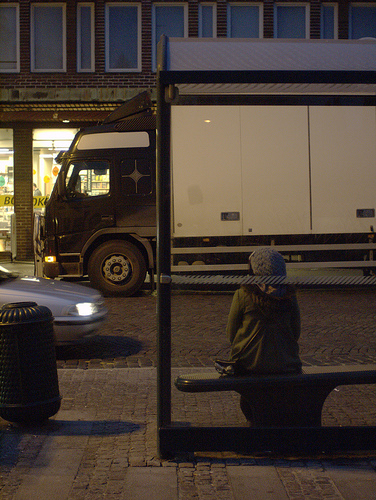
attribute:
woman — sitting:
[214, 246, 309, 378]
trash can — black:
[0, 297, 64, 426]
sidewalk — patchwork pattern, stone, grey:
[5, 364, 373, 498]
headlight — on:
[70, 302, 102, 318]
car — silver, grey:
[5, 262, 108, 350]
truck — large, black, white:
[37, 36, 373, 296]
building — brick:
[0, 0, 373, 264]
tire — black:
[82, 237, 146, 298]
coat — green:
[216, 282, 303, 374]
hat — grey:
[247, 245, 288, 287]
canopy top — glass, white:
[160, 35, 375, 74]